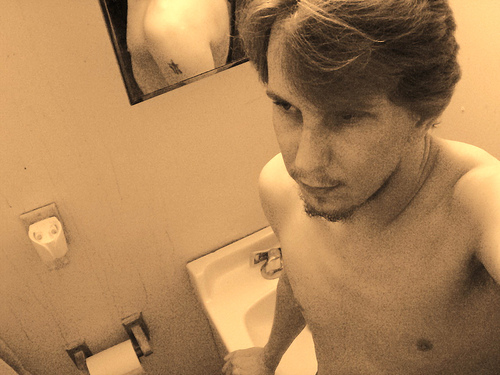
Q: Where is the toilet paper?
A: On the wall.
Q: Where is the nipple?
A: On the man.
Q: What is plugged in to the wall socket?
A: Air freshener.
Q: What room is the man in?
A: Bathroom.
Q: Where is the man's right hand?
A: On the sink.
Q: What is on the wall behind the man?
A: Mirror.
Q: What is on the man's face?
A: Beard and mustache.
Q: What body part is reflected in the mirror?
A: Shoulder.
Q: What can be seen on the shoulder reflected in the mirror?
A: Tattoo.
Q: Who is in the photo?
A: Man.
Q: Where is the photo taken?
A: Bathroom.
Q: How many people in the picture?
A: One.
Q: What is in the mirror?
A: The man's shoulder.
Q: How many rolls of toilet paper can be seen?
A: One.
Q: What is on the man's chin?
A: Beard.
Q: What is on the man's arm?
A: Tattoo.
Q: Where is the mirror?
A: On the wall.